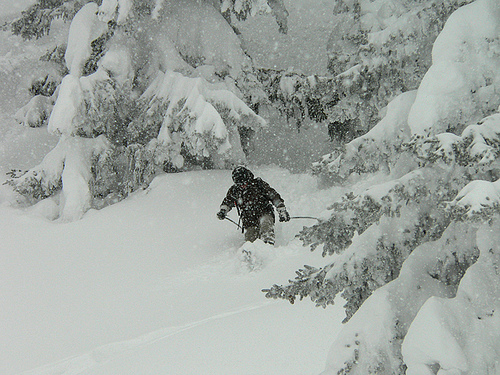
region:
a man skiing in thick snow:
[214, 157, 311, 265]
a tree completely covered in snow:
[16, 1, 271, 237]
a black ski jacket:
[209, 160, 303, 265]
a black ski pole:
[282, 209, 337, 228]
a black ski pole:
[213, 202, 251, 229]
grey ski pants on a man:
[246, 204, 280, 258]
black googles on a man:
[234, 168, 249, 188]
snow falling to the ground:
[8, 8, 480, 259]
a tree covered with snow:
[323, 52, 496, 354]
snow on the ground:
[10, 157, 373, 371]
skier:
[214, 158, 279, 236]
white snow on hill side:
[62, 263, 117, 303]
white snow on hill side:
[239, 353, 268, 370]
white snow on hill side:
[266, 325, 292, 360]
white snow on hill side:
[211, 357, 234, 374]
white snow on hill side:
[241, 300, 266, 334]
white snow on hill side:
[157, 289, 194, 321]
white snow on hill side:
[103, 314, 148, 337]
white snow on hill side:
[163, 255, 199, 291]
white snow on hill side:
[144, 241, 196, 288]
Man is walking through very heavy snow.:
[2, 1, 498, 373]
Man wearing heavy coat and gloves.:
[212, 163, 320, 269]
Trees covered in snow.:
[0, 1, 498, 373]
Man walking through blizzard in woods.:
[1, 0, 498, 374]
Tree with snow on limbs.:
[0, 0, 293, 221]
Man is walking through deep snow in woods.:
[0, 1, 497, 373]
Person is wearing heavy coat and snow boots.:
[213, 165, 320, 272]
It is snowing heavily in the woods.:
[1, 0, 496, 193]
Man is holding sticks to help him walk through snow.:
[212, 165, 329, 274]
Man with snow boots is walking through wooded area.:
[2, 1, 498, 373]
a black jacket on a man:
[218, 167, 286, 236]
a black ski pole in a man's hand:
[281, 210, 329, 230]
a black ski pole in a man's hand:
[218, 206, 248, 238]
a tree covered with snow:
[33, 0, 271, 185]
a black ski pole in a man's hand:
[291, 46, 494, 367]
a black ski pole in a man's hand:
[293, 6, 401, 163]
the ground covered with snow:
[12, 159, 358, 371]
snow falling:
[143, 10, 411, 192]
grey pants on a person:
[241, 206, 279, 251]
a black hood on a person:
[229, 160, 253, 187]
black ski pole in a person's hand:
[277, 210, 328, 228]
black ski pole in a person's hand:
[221, 206, 249, 238]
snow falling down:
[18, 9, 493, 192]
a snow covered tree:
[27, 6, 282, 181]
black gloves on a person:
[276, 207, 293, 227]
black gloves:
[211, 203, 230, 217]